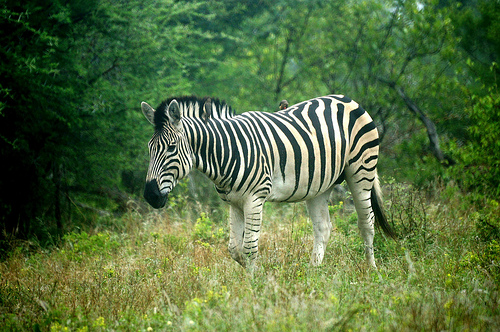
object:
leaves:
[125, 30, 206, 89]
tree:
[275, 7, 447, 86]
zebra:
[139, 95, 396, 268]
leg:
[307, 191, 331, 263]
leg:
[346, 168, 377, 269]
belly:
[263, 163, 344, 204]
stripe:
[320, 95, 335, 186]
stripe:
[346, 103, 363, 141]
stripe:
[363, 150, 377, 165]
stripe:
[255, 110, 287, 177]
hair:
[153, 96, 239, 128]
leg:
[239, 196, 266, 276]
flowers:
[200, 288, 215, 303]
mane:
[147, 90, 234, 130]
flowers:
[373, 251, 484, 330]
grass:
[58, 235, 225, 322]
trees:
[3, 2, 498, 247]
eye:
[166, 145, 177, 152]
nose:
[142, 178, 170, 210]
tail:
[367, 175, 406, 253]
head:
[142, 102, 193, 210]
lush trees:
[7, 2, 434, 124]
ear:
[140, 101, 156, 128]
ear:
[167, 99, 184, 123]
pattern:
[264, 125, 322, 149]